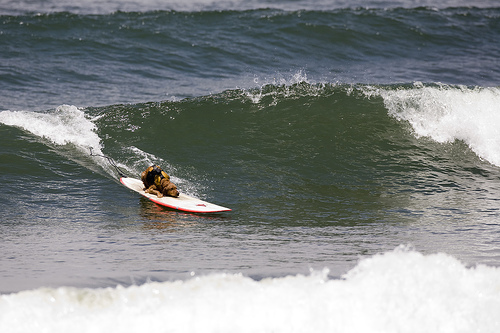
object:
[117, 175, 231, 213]
surfboard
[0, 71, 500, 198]
wave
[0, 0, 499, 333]
water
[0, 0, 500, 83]
wave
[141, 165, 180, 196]
dog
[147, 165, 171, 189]
life jacket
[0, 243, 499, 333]
wave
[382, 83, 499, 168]
seafoam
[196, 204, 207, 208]
logo